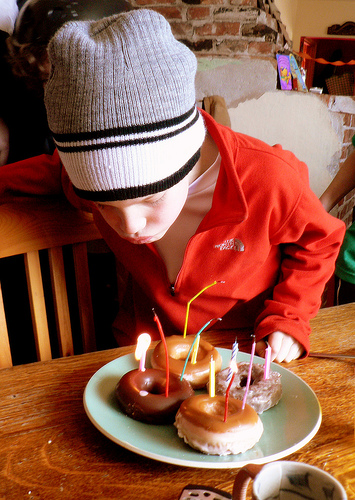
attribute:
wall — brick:
[130, 0, 354, 228]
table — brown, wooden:
[1, 300, 352, 497]